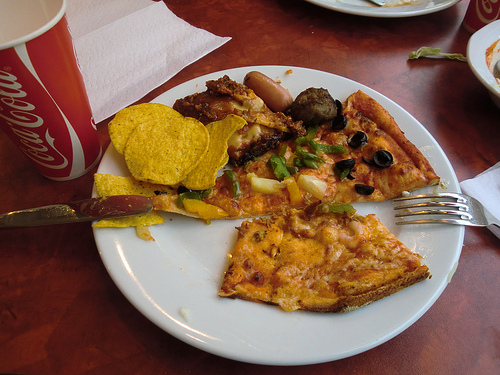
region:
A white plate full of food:
[88, 50, 465, 373]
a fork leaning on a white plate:
[385, 188, 482, 242]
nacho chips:
[100, 101, 222, 205]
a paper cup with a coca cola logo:
[1, 3, 103, 173]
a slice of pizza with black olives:
[241, 103, 430, 212]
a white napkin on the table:
[104, 0, 238, 132]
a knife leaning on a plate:
[0, 187, 159, 250]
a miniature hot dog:
[235, 71, 297, 114]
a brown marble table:
[3, 234, 97, 366]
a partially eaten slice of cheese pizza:
[228, 217, 411, 324]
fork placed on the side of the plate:
[394, 193, 499, 246]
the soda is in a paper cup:
[3, 1, 105, 184]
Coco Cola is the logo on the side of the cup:
[2, 68, 69, 183]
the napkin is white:
[67, 1, 244, 124]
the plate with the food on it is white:
[99, 66, 476, 365]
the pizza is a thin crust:
[226, 206, 421, 309]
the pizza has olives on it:
[368, 151, 391, 173]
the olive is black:
[373, 147, 394, 176]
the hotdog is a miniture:
[243, 70, 296, 115]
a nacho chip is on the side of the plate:
[106, 104, 208, 187]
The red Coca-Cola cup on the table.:
[1, 3, 107, 188]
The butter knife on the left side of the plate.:
[9, 192, 163, 227]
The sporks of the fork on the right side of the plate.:
[386, 176, 471, 232]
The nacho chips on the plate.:
[107, 82, 237, 227]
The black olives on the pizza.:
[330, 121, 398, 191]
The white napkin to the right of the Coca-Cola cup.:
[92, 1, 209, 129]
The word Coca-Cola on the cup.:
[1, 65, 62, 196]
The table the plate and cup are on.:
[0, 5, 497, 372]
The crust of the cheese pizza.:
[217, 277, 434, 311]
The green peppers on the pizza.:
[251, 128, 359, 185]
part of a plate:
[168, 252, 202, 292]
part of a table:
[426, 301, 469, 354]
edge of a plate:
[169, 322, 217, 357]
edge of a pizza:
[226, 277, 279, 329]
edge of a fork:
[395, 210, 438, 232]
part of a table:
[439, 261, 487, 314]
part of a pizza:
[303, 283, 353, 325]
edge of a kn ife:
[68, 208, 110, 228]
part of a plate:
[341, 317, 381, 332]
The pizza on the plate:
[156, 89, 446, 219]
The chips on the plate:
[103, 105, 238, 232]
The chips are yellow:
[93, 104, 237, 222]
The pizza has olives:
[163, 95, 448, 217]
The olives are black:
[329, 127, 398, 191]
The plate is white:
[93, 60, 460, 370]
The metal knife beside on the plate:
[6, 193, 156, 226]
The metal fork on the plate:
[389, 184, 499, 254]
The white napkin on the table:
[74, 3, 234, 129]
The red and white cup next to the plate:
[0, 0, 107, 176]